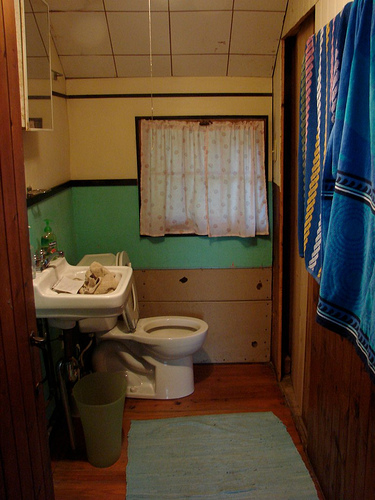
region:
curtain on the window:
[136, 116, 274, 241]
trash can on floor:
[72, 369, 128, 469]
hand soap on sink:
[38, 218, 59, 259]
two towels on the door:
[297, 0, 372, 375]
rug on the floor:
[123, 410, 314, 498]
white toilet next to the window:
[77, 251, 208, 401]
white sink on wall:
[30, 240, 136, 336]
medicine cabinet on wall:
[11, 0, 58, 135]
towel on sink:
[71, 260, 117, 295]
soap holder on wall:
[26, 182, 51, 198]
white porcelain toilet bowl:
[91, 310, 213, 400]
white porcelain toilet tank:
[73, 244, 119, 335]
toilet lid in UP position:
[113, 247, 141, 328]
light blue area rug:
[123, 401, 323, 499]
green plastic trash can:
[67, 370, 139, 468]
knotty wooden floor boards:
[45, 359, 330, 498]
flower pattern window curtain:
[137, 114, 281, 251]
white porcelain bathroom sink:
[27, 249, 134, 316]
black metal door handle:
[26, 328, 52, 350]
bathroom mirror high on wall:
[17, 0, 57, 133]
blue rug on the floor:
[120, 408, 280, 499]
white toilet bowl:
[144, 296, 206, 411]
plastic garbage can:
[82, 374, 129, 474]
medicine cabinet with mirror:
[20, 69, 54, 149]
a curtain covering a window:
[125, 109, 268, 254]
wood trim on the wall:
[36, 169, 141, 207]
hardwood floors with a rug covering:
[183, 366, 302, 498]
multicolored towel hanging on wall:
[302, 3, 365, 239]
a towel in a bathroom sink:
[68, 250, 143, 325]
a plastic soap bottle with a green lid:
[40, 217, 60, 265]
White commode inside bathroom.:
[89, 310, 212, 398]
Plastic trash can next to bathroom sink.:
[69, 367, 133, 469]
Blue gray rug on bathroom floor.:
[122, 409, 315, 498]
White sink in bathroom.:
[34, 253, 133, 318]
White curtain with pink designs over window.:
[132, 111, 275, 242]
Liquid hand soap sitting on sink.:
[40, 217, 57, 256]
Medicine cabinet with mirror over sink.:
[15, 2, 59, 131]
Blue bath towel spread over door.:
[299, 0, 374, 380]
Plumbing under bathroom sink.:
[51, 331, 90, 452]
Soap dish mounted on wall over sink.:
[25, 182, 53, 201]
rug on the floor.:
[199, 436, 270, 468]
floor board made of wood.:
[81, 480, 108, 490]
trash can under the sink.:
[94, 374, 120, 445]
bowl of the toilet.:
[154, 321, 197, 338]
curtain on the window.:
[149, 144, 249, 210]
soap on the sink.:
[47, 220, 55, 261]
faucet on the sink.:
[34, 250, 52, 266]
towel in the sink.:
[93, 268, 112, 292]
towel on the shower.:
[327, 217, 360, 287]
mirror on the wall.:
[29, 23, 41, 112]